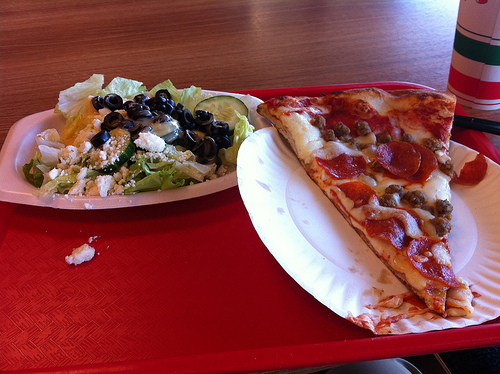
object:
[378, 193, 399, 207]
sausage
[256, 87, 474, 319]
slice of pizza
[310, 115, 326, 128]
sausage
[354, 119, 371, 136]
sausage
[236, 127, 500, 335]
plate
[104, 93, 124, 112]
olive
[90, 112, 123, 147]
two olives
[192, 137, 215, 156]
olives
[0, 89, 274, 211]
plate of salad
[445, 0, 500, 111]
cup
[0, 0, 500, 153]
table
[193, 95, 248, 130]
cucumber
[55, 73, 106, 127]
lettuce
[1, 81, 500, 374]
tray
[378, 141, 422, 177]
pepperoni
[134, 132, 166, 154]
cheese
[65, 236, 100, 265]
cheese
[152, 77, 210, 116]
lettuce